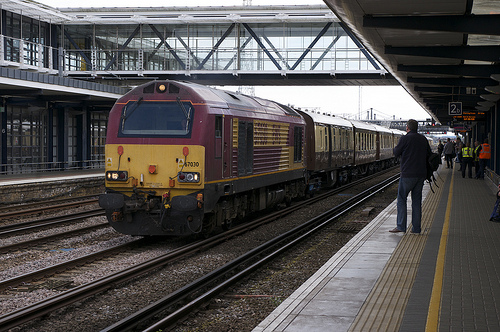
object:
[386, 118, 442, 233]
man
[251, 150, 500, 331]
platform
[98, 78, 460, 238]
train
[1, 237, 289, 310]
gravel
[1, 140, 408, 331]
tracks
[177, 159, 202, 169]
numbers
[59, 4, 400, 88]
walkway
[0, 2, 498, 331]
station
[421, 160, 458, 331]
line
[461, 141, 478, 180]
men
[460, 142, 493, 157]
uniforms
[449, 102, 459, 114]
2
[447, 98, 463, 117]
sign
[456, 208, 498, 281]
pattern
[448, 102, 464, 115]
2b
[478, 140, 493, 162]
jacket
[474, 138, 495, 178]
man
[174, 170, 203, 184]
headlights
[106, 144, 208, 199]
panel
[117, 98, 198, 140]
windshield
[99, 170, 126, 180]
headlight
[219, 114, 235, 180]
door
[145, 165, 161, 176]
object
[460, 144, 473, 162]
jacket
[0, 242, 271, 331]
ground